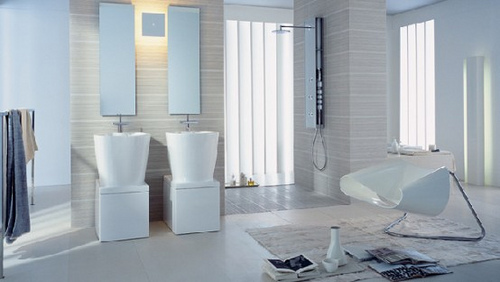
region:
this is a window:
[393, 22, 430, 147]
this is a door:
[224, 18, 283, 176]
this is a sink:
[91, 135, 156, 182]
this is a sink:
[164, 120, 212, 185]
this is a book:
[250, 233, 329, 273]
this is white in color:
[97, 0, 142, 125]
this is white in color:
[160, 2, 206, 115]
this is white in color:
[84, 128, 150, 240]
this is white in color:
[159, 109, 234, 227]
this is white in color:
[341, 143, 445, 223]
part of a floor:
[207, 228, 216, 245]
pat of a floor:
[196, 257, 221, 280]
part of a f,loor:
[189, 250, 204, 267]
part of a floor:
[188, 240, 214, 271]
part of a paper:
[299, 255, 306, 262]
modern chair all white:
[330, 153, 457, 220]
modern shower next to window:
[268, 14, 328, 171]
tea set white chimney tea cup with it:
[313, 219, 350, 276]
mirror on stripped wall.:
[90, 21, 152, 127]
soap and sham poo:
[225, 170, 260, 192]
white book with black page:
[262, 249, 320, 280]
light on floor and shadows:
[38, 185, 78, 240]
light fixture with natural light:
[136, 7, 168, 43]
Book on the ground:
[261, 247, 322, 279]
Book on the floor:
[260, 249, 322, 280]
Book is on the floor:
[259, 251, 322, 280]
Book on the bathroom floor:
[257, 249, 324, 280]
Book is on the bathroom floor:
[259, 252, 316, 279]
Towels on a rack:
[1, 102, 51, 242]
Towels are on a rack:
[0, 102, 49, 243]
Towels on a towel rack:
[0, 101, 47, 241]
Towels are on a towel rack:
[0, 107, 46, 247]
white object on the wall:
[96, 1, 140, 121]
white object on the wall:
[166, 0, 198, 122]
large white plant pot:
[158, 126, 225, 181]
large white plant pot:
[86, 123, 153, 184]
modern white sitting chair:
[334, 147, 484, 247]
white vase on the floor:
[319, 220, 348, 264]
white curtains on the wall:
[219, 17, 294, 181]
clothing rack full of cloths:
[0, 98, 42, 248]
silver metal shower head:
[271, 19, 293, 41]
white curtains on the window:
[396, 23, 437, 146]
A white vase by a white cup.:
[324, 224, 347, 266]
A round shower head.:
[272, 28, 290, 35]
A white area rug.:
[244, 214, 499, 280]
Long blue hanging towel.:
[0, 109, 32, 241]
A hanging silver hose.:
[310, 124, 329, 171]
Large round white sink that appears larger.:
[93, 131, 151, 188]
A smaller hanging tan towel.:
[17, 108, 40, 164]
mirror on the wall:
[96, 1, 141, 123]